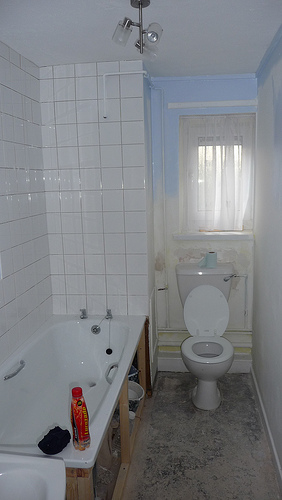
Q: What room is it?
A: It is a bathroom.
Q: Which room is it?
A: It is a bathroom.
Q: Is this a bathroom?
A: Yes, it is a bathroom.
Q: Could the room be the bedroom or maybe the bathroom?
A: It is the bathroom.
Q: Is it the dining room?
A: No, it is the bathroom.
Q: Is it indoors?
A: Yes, it is indoors.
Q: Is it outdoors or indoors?
A: It is indoors.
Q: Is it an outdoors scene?
A: No, it is indoors.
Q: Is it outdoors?
A: No, it is indoors.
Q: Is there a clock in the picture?
A: No, there are no clocks.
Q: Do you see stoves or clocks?
A: No, there are no clocks or stoves.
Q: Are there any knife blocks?
A: No, there are no knife blocks.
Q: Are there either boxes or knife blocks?
A: No, there are no knife blocks or boxes.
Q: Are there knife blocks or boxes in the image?
A: No, there are no knife blocks or boxes.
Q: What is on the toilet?
A: The paper is on the toilet.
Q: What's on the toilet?
A: The paper is on the toilet.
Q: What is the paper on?
A: The paper is on the toilet.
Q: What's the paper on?
A: The paper is on the toilet.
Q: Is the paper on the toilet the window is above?
A: Yes, the paper is on the toilet.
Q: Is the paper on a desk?
A: No, the paper is on the toilet.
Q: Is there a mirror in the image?
A: No, there are no mirrors.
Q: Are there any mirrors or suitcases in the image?
A: No, there are no mirrors or suitcases.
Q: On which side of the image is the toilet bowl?
A: The bowl is on the right of the image.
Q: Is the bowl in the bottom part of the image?
A: Yes, the bowl is in the bottom of the image.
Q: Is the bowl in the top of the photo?
A: No, the bowl is in the bottom of the image.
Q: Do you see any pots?
A: No, there are no pots.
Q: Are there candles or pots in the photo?
A: No, there are no pots or candles.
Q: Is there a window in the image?
A: Yes, there is a window.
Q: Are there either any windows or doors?
A: Yes, there is a window.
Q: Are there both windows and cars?
A: No, there is a window but no cars.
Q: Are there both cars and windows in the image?
A: No, there is a window but no cars.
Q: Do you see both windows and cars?
A: No, there is a window but no cars.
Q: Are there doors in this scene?
A: No, there are no doors.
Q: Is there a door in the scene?
A: No, there are no doors.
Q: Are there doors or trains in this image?
A: No, there are no doors or trains.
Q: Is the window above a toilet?
A: Yes, the window is above a toilet.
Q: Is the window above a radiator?
A: No, the window is above a toilet.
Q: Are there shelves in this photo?
A: No, there are no shelves.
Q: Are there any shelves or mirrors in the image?
A: No, there are no shelves or mirrors.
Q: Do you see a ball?
A: No, there are no balls.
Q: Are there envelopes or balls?
A: No, there are no balls or envelopes.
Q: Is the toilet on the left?
A: No, the toilet is on the right of the image.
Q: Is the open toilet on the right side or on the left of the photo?
A: The toilet is on the right of the image.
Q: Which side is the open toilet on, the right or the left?
A: The toilet is on the right of the image.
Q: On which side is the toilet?
A: The toilet is on the right of the image.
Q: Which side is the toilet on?
A: The toilet is on the right of the image.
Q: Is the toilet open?
A: Yes, the toilet is open.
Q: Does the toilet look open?
A: Yes, the toilet is open.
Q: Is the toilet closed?
A: No, the toilet is open.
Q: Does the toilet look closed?
A: No, the toilet is open.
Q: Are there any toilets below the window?
A: Yes, there is a toilet below the window.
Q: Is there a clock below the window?
A: No, there is a toilet below the window.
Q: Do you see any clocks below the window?
A: No, there is a toilet below the window.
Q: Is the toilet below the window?
A: Yes, the toilet is below the window.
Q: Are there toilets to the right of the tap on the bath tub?
A: Yes, there is a toilet to the right of the tap.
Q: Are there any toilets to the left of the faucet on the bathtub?
A: No, the toilet is to the right of the tap.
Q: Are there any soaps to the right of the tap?
A: No, there is a toilet to the right of the tap.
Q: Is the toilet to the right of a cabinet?
A: No, the toilet is to the right of the tap.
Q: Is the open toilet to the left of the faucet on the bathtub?
A: No, the toilet is to the right of the faucet.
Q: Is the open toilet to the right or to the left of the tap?
A: The toilet is to the right of the tap.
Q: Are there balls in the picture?
A: No, there are no balls.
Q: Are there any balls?
A: No, there are no balls.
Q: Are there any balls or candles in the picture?
A: No, there are no balls or candles.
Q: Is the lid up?
A: Yes, the lid is up.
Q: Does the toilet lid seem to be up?
A: Yes, the lid is up.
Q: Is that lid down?
A: No, the lid is up.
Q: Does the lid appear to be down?
A: No, the lid is up.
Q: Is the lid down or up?
A: The lid is up.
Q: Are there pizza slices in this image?
A: No, there are no pizza slices.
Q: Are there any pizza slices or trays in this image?
A: No, there are no pizza slices or trays.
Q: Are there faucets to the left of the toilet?
A: Yes, there is a faucet to the left of the toilet.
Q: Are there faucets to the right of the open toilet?
A: No, the faucet is to the left of the toilet.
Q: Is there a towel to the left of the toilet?
A: No, there is a faucet to the left of the toilet.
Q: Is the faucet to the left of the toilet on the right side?
A: Yes, the faucet is to the left of the toilet.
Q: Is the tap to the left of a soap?
A: No, the tap is to the left of the toilet.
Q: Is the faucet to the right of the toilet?
A: No, the faucet is to the left of the toilet.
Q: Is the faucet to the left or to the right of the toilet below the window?
A: The faucet is to the left of the toilet.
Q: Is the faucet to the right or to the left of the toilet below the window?
A: The faucet is to the left of the toilet.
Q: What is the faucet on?
A: The faucet is on the bathtub.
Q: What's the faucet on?
A: The faucet is on the bathtub.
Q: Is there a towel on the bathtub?
A: No, there is a faucet on the bathtub.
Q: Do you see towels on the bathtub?
A: No, there is a faucet on the bathtub.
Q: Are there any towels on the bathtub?
A: No, there is a faucet on the bathtub.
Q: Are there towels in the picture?
A: No, there are no towels.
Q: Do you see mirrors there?
A: No, there are no mirrors.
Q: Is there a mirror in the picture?
A: No, there are no mirrors.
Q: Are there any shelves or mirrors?
A: No, there are no mirrors or shelves.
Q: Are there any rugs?
A: No, there are no rugs.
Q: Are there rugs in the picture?
A: No, there are no rugs.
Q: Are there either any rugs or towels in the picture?
A: No, there are no rugs or towels.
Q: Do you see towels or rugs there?
A: No, there are no rugs or towels.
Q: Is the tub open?
A: Yes, the tub is open.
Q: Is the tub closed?
A: No, the tub is open.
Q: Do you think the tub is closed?
A: No, the tub is open.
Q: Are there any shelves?
A: No, there are no shelves.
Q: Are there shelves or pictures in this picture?
A: No, there are no shelves or pictures.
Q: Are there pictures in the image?
A: No, there are no pictures.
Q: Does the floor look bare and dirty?
A: Yes, the floor is bare and dirty.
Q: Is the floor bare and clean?
A: No, the floor is bare but dirty.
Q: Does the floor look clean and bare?
A: No, the floor is bare but dirty.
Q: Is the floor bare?
A: Yes, the floor is bare.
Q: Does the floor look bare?
A: Yes, the floor is bare.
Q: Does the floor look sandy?
A: No, the floor is bare.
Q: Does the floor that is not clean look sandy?
A: No, the floor is bare.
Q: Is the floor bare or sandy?
A: The floor is bare.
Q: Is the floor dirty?
A: Yes, the floor is dirty.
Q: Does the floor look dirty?
A: Yes, the floor is dirty.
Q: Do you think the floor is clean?
A: No, the floor is dirty.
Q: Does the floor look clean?
A: No, the floor is dirty.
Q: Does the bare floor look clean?
A: No, the floor is dirty.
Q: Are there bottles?
A: Yes, there is a bottle.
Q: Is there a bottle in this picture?
A: Yes, there is a bottle.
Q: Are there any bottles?
A: Yes, there is a bottle.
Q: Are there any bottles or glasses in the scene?
A: Yes, there is a bottle.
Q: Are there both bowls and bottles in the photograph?
A: Yes, there are both a bottle and a bowl.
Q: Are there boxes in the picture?
A: No, there are no boxes.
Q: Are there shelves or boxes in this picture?
A: No, there are no boxes or shelves.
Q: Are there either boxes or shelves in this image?
A: No, there are no boxes or shelves.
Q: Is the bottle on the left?
A: Yes, the bottle is on the left of the image.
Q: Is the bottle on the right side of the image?
A: No, the bottle is on the left of the image.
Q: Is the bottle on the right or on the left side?
A: The bottle is on the left of the image.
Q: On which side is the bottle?
A: The bottle is on the left of the image.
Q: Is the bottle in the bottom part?
A: Yes, the bottle is in the bottom of the image.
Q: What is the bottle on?
A: The bottle is on the bathtub.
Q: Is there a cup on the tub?
A: No, there is a bottle on the tub.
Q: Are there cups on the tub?
A: No, there is a bottle on the tub.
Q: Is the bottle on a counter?
A: No, the bottle is on a bathtub.